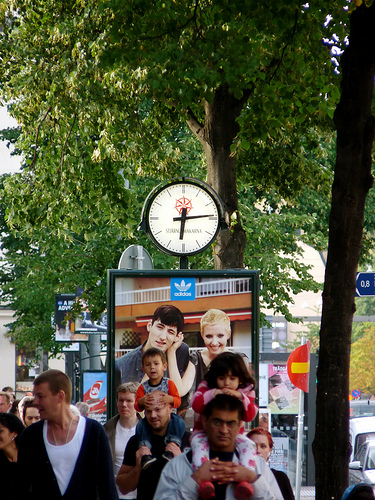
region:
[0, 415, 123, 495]
the man is wearing black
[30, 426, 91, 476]
the man is wearing black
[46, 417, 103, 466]
the man is wearing black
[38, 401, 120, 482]
the man is wearing black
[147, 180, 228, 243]
this is a clock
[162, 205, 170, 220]
the clock is white in color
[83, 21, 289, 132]
this is a tree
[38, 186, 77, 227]
the leaves are green in color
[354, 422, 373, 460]
this is a car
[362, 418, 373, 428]
the car is white in color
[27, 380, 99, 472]
this is a man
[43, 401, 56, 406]
the man is light skinned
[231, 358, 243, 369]
the hair is long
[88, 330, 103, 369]
this is a pole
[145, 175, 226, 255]
White clock with black hands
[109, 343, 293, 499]
Two men carrying children on their shoulders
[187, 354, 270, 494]
Little girl on dad's shoulders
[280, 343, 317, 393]
Red and yellow sign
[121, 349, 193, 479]
Little boy on dad's shoulders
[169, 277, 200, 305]
White and blue Adidas symbol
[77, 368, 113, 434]
Blue sign with red and white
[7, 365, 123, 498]
Man in black sweater and white shirt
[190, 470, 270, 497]
Red shoes on little girl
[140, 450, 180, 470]
Black and white shoes on little boy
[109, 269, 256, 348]
People on a billboard.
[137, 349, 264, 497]
Kids sitting on shoulders.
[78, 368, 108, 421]
A billboard on a sign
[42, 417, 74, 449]
A man with a necklace.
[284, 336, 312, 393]
The street sign posted.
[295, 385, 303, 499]
The pole for the sign.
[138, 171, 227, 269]
The clock on the pole.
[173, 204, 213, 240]
Hands of the clock.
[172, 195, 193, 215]
Compass on the clock.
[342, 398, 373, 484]
cars parked on the shoulder.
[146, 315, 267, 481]
the man is carrying baby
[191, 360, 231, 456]
the man is carrying baby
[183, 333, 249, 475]
the man is carrying baby